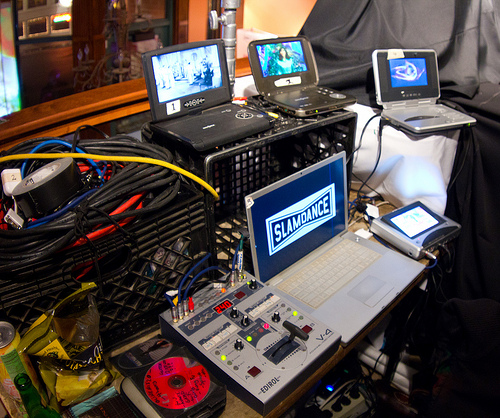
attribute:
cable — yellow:
[24, 143, 222, 197]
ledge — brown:
[4, 61, 223, 146]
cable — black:
[43, 132, 137, 210]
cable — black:
[9, 137, 213, 259]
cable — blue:
[63, 157, 118, 204]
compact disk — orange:
[142, 355, 209, 411]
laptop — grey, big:
[227, 144, 436, 349]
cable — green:
[15, 158, 152, 241]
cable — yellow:
[0, 145, 230, 207]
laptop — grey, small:
[244, 147, 425, 346]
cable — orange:
[92, 192, 130, 250]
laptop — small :
[142, 37, 274, 156]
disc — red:
[126, 350, 211, 417]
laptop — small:
[371, 46, 476, 138]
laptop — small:
[140, 39, 271, 146]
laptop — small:
[244, 33, 355, 118]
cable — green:
[174, 251, 214, 305]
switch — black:
[268, 318, 309, 367]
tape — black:
[6, 154, 82, 224]